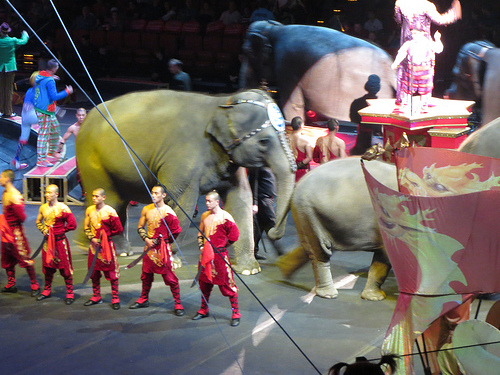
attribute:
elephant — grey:
[76, 86, 300, 277]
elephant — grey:
[243, 21, 400, 134]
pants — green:
[1, 70, 16, 115]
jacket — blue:
[32, 73, 68, 115]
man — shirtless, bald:
[58, 106, 87, 150]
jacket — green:
[1, 37, 30, 73]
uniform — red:
[1, 190, 244, 319]